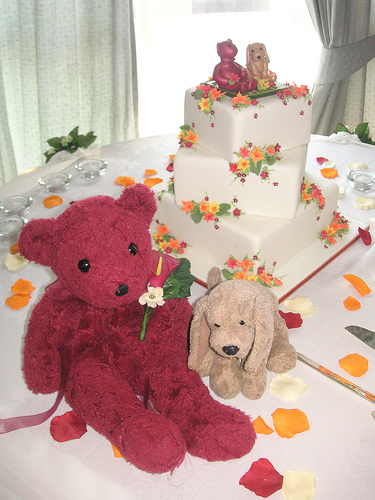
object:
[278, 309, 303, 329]
rose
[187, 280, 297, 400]
animal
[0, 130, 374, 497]
table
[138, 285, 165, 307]
flower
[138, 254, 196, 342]
boutonniere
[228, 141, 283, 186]
flower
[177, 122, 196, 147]
flower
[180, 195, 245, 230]
flower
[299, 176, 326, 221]
flower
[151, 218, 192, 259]
flower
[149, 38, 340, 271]
cake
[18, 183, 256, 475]
animal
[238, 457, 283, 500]
flower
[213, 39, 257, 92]
figurines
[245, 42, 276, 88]
figurines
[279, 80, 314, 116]
flowers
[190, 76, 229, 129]
flowers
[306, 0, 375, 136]
curtain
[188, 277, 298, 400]
toys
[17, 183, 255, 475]
toys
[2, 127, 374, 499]
tablecloth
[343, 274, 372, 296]
petal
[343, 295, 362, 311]
petal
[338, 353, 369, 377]
petal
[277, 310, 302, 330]
petal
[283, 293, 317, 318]
petal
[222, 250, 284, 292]
flower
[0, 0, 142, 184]
curtains